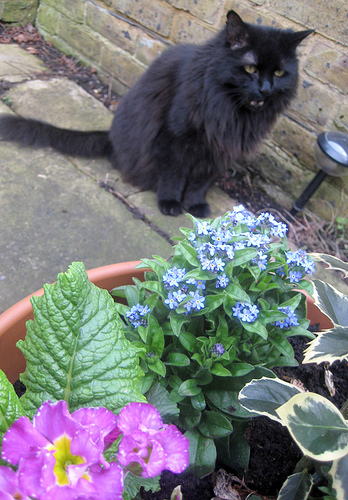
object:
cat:
[0, 8, 316, 216]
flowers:
[1, 396, 190, 498]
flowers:
[232, 300, 261, 323]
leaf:
[274, 390, 347, 460]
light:
[287, 130, 347, 223]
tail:
[1, 113, 110, 158]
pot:
[1, 257, 347, 495]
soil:
[9, 323, 346, 500]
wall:
[0, 0, 347, 237]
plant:
[0, 205, 348, 500]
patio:
[1, 39, 347, 326]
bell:
[248, 99, 263, 107]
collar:
[205, 34, 300, 108]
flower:
[213, 342, 224, 353]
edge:
[274, 409, 347, 461]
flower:
[116, 402, 161, 438]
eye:
[243, 66, 257, 76]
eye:
[273, 70, 283, 78]